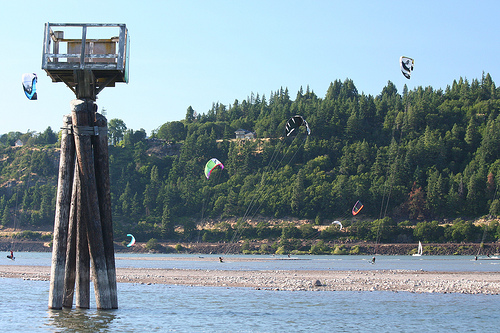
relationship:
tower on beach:
[40, 21, 127, 313] [2, 249, 494, 331]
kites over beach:
[21, 54, 416, 217] [4, 270, 497, 289]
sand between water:
[346, 270, 458, 283] [285, 290, 440, 328]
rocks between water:
[406, 278, 474, 294] [285, 290, 440, 328]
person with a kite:
[1, 243, 25, 267] [15, 64, 47, 106]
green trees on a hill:
[110, 68, 498, 223] [0, 69, 499, 227]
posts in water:
[43, 97, 165, 325] [188, 276, 372, 322]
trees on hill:
[408, 114, 493, 209] [3, 80, 497, 240]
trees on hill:
[246, 141, 402, 209] [3, 80, 497, 240]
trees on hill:
[206, 76, 401, 131] [3, 80, 497, 240]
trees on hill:
[421, 70, 499, 113] [3, 80, 497, 240]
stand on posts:
[42, 21, 128, 97] [48, 100, 118, 309]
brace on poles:
[61, 122, 106, 136] [52, 103, 116, 311]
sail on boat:
[418, 237, 423, 253] [411, 239, 423, 256]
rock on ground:
[310, 269, 327, 287] [8, 261, 498, 295]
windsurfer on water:
[407, 238, 424, 260] [4, 250, 497, 331]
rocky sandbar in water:
[106, 260, 498, 301] [4, 250, 497, 331]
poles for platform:
[41, 99, 140, 316] [31, 16, 133, 102]